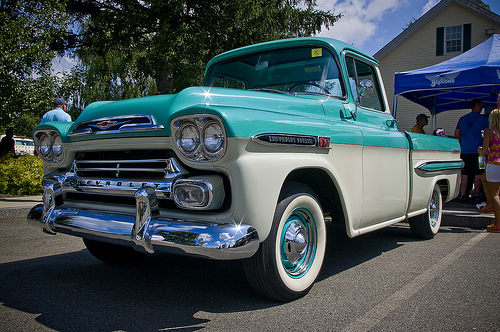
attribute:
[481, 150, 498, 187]
shorts — white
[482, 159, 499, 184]
shorts — denim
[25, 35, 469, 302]
truck — vintage, cream, blue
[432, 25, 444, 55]
shutter — black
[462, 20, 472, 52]
shutter — black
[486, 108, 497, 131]
hair — blonde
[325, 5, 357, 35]
cloud — white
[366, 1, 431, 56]
sky — blue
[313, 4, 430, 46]
clouds — white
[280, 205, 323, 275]
hubcap — blue, silver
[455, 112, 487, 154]
shirt — blue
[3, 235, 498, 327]
parking lot — paved, black top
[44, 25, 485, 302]
truck — white, blue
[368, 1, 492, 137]
siding — tan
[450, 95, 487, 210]
man — tall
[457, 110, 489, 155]
shirt — light blue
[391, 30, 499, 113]
tent roof — blue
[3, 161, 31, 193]
bush — yellow green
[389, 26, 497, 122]
tent — blue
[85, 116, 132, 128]
logo — car company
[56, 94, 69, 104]
cap — navy blue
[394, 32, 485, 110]
roof — blue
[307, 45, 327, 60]
sticker — yellow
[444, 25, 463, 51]
window — white